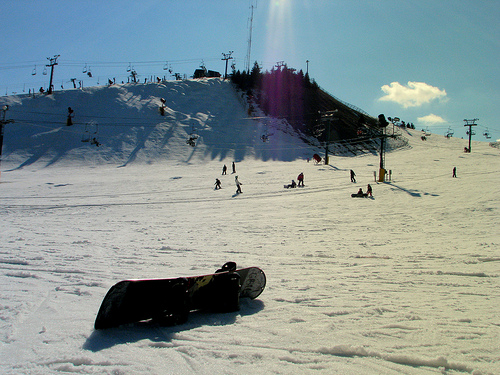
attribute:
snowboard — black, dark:
[87, 258, 274, 333]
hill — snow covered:
[188, 82, 264, 115]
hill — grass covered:
[270, 69, 321, 113]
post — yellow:
[376, 169, 387, 182]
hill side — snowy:
[196, 75, 237, 128]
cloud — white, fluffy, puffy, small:
[370, 69, 450, 109]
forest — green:
[275, 79, 325, 113]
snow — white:
[178, 121, 216, 133]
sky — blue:
[284, 9, 388, 44]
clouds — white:
[368, 61, 458, 127]